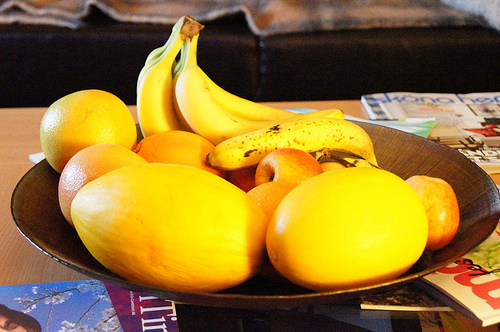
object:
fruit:
[38, 28, 464, 291]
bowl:
[11, 118, 492, 306]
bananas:
[134, 14, 185, 137]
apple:
[252, 146, 317, 186]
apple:
[406, 173, 463, 249]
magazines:
[372, 90, 498, 146]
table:
[1, 101, 500, 332]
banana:
[205, 117, 374, 168]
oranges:
[59, 144, 146, 217]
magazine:
[1, 283, 175, 332]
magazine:
[366, 283, 457, 312]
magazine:
[445, 264, 500, 324]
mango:
[266, 169, 423, 291]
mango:
[72, 164, 269, 292]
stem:
[160, 14, 206, 58]